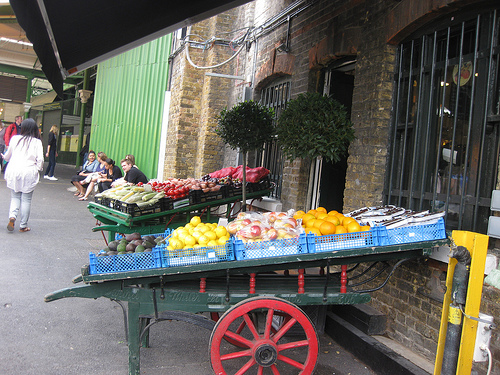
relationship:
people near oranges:
[86, 142, 155, 186] [309, 210, 363, 239]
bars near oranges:
[397, 43, 482, 162] [309, 210, 363, 239]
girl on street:
[4, 111, 58, 246] [16, 235, 99, 367]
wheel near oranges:
[219, 290, 319, 368] [309, 210, 363, 239]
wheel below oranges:
[219, 290, 319, 368] [309, 210, 363, 239]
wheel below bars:
[219, 290, 319, 368] [397, 43, 482, 162]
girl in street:
[4, 111, 58, 246] [16, 235, 99, 367]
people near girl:
[86, 142, 155, 186] [4, 111, 58, 246]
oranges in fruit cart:
[309, 210, 363, 239] [41, 199, 446, 373]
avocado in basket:
[126, 231, 138, 240] [86, 224, 169, 274]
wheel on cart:
[204, 293, 318, 373] [44, 204, 451, 367]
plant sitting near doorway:
[273, 88, 356, 208] [317, 66, 353, 215]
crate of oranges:
[304, 226, 371, 255] [309, 210, 363, 239]